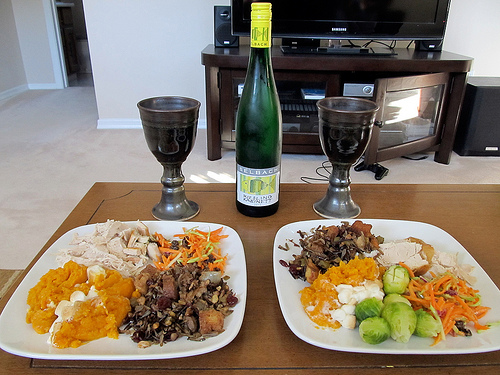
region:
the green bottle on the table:
[236, 4, 281, 221]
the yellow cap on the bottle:
[245, 1, 276, 22]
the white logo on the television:
[330, 21, 350, 35]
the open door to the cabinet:
[369, 70, 444, 160]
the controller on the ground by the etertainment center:
[355, 156, 391, 181]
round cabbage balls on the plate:
[348, 269, 445, 341]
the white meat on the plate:
[59, 209, 163, 284]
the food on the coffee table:
[0, 216, 497, 367]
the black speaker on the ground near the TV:
[452, 77, 499, 154]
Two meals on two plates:
[25, 210, 497, 357]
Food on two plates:
[32, 217, 498, 362]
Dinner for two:
[6, 208, 497, 367]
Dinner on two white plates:
[0, 205, 497, 372]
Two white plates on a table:
[3, 210, 499, 367]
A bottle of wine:
[233, 2, 290, 221]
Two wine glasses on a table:
[126, 84, 392, 226]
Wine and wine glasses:
[125, 0, 383, 220]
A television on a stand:
[220, 2, 475, 65]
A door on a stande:
[363, 70, 469, 163]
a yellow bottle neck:
[249, 3, 273, 45]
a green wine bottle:
[236, 0, 281, 217]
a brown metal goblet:
[137, 97, 204, 219]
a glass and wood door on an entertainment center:
[363, 72, 443, 161]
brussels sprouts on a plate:
[357, 265, 440, 342]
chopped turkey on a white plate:
[67, 218, 158, 269]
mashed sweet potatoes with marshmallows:
[25, 260, 126, 345]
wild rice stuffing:
[129, 266, 237, 339]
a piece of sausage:
[159, 275, 178, 300]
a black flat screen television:
[229, 0, 451, 40]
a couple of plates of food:
[0, 217, 498, 353]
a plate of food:
[274, 222, 496, 357]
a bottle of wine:
[238, 23, 284, 213]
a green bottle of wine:
[234, 27, 280, 214]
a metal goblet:
[135, 96, 200, 222]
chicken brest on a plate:
[63, 223, 163, 278]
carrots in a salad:
[439, 273, 482, 335]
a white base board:
[27, 78, 67, 92]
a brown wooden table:
[1, 183, 499, 370]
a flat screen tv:
[231, 0, 453, 37]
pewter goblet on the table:
[130, 89, 207, 219]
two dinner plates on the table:
[0, 223, 499, 359]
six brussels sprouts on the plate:
[350, 263, 438, 343]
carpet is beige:
[0, 90, 61, 217]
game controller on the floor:
[351, 156, 386, 178]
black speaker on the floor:
[460, 78, 499, 163]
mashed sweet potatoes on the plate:
[21, 260, 122, 350]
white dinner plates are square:
[5, 220, 496, 355]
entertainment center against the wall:
[200, 0, 470, 160]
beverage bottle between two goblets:
[136, 2, 379, 217]